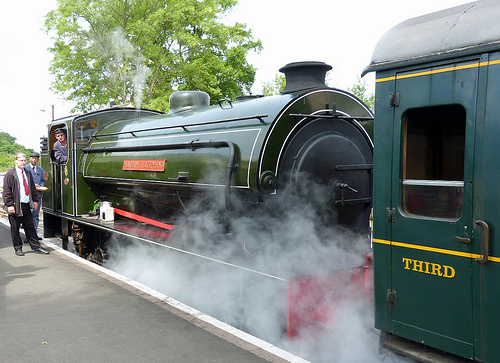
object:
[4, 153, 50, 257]
man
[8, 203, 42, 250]
black pants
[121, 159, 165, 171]
sign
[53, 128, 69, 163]
man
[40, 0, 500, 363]
train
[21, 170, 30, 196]
tie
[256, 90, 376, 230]
front